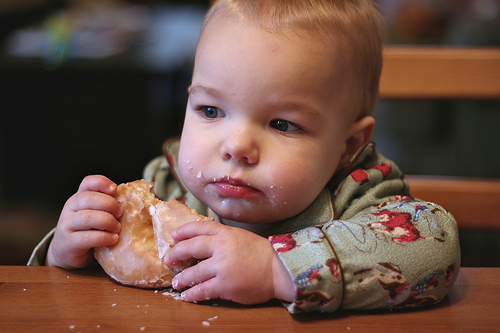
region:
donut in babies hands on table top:
[91, 177, 219, 296]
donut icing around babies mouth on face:
[178, 150, 298, 220]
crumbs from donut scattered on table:
[16, 269, 241, 331]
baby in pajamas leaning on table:
[21, 2, 481, 320]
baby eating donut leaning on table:
[22, 2, 467, 321]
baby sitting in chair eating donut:
[21, 6, 495, 315]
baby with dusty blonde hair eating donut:
[23, 3, 466, 320]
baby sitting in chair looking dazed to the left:
[11, 5, 496, 319]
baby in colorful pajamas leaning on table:
[22, 5, 472, 322]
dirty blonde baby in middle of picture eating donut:
[19, 5, 476, 318]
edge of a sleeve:
[268, 235, 301, 286]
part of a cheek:
[286, 168, 325, 225]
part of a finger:
[128, 236, 188, 292]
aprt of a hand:
[213, 229, 250, 307]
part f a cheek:
[286, 159, 316, 206]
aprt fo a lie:
[248, 235, 282, 282]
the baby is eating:
[44, 40, 455, 310]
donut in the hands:
[60, 193, 243, 310]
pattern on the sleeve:
[285, 200, 455, 315]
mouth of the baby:
[203, 182, 253, 204]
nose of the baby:
[217, 135, 264, 169]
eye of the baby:
[184, 85, 320, 143]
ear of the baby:
[350, 108, 377, 174]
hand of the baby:
[54, 164, 110, 284]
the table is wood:
[15, 288, 97, 324]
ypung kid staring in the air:
[148, 24, 355, 331]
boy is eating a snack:
[96, 53, 354, 289]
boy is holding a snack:
[65, 164, 259, 327]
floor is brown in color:
[46, 266, 150, 331]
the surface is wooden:
[58, 264, 113, 331]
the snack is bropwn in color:
[116, 203, 190, 283]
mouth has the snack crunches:
[183, 150, 277, 217]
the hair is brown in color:
[321, 9, 396, 85]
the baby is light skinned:
[219, 252, 291, 307]